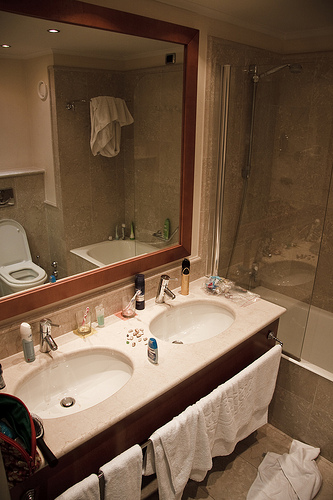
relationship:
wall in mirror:
[51, 116, 108, 223] [84, 12, 196, 267]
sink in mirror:
[156, 298, 227, 353] [84, 12, 196, 267]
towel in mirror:
[93, 92, 130, 169] [84, 12, 196, 267]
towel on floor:
[273, 445, 313, 491] [224, 464, 248, 496]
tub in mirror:
[75, 245, 111, 268] [84, 12, 196, 267]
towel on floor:
[93, 92, 130, 169] [224, 464, 248, 496]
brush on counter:
[125, 293, 150, 308] [161, 347, 188, 381]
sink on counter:
[156, 298, 227, 353] [161, 347, 188, 381]